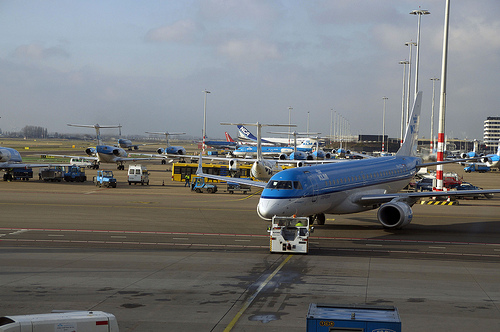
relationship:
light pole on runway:
[440, 9, 464, 174] [95, 210, 183, 242]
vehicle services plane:
[267, 211, 312, 256] [255, 142, 433, 231]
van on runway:
[132, 164, 152, 183] [95, 210, 183, 242]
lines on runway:
[54, 187, 107, 225] [95, 210, 183, 242]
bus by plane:
[176, 164, 258, 209] [255, 142, 433, 231]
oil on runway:
[241, 260, 297, 317] [95, 210, 183, 242]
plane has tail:
[255, 142, 433, 231] [395, 104, 432, 178]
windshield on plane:
[284, 179, 299, 187] [255, 142, 433, 231]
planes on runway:
[206, 121, 318, 157] [95, 210, 183, 242]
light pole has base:
[440, 9, 464, 174] [419, 198, 454, 216]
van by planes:
[132, 164, 152, 183] [206, 121, 318, 157]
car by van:
[94, 170, 126, 193] [132, 164, 152, 183]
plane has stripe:
[255, 142, 433, 231] [324, 185, 363, 199]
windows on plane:
[357, 174, 385, 182] [255, 142, 433, 231]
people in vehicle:
[281, 211, 309, 224] [267, 211, 312, 256]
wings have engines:
[387, 188, 495, 196] [378, 200, 416, 232]